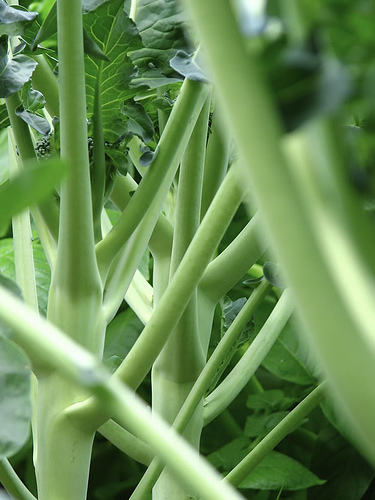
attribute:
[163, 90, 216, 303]
stalk — green , Small 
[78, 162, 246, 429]
stem — green, long, plant's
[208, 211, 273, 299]
stem — green, long, plant's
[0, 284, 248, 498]
stem — green, long, plant's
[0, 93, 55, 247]
stem — green, long, plant's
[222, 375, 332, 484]
stem — green, long, plant's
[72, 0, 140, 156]
broccoli leaf — fresh , green 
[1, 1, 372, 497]
tree — banana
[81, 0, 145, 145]
leaf — flag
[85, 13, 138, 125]
leaf — green, broccoli's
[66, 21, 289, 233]
flower — plant's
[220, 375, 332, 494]
stem — long, green, plant's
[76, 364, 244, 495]
stem — fresh, green 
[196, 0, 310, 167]
stem — long, green, of plant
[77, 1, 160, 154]
leaf — green , fresh 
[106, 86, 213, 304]
stem — light-green, broccoli's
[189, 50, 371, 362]
stem — light-green, broccoli's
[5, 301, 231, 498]
stem — light-green, broccoli's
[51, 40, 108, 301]
stem — light-green, broccoli's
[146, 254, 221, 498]
stem — light-green, broccoli's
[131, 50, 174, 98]
leaf — wind blown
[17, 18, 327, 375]
stem — plant's, long, green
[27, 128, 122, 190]
stock — small, green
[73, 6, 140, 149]
leaf — veined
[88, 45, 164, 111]
banana leaf — wind torn, flag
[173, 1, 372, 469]
plant — green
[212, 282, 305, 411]
stalk — Small , green 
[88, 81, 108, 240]
stem — green, long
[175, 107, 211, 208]
stock — small , green 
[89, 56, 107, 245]
stem — flag leaf's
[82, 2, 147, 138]
broccoli leaf — green, fresh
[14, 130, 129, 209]
banana tree — budded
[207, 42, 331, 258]
broccoli — green , fresh 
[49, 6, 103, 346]
stem — bent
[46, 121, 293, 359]
plant — green , Small 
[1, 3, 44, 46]
broccoli leaf — green , fresh 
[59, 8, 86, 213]
green stem — long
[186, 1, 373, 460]
plant stock — small, green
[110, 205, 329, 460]
broccoli — green , fresh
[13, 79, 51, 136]
banana leaf — curled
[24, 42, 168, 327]
plant — green, small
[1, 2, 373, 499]
stem — green, banana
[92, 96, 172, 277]
plant — Small , green 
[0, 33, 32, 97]
leaf — veined, green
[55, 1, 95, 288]
stem — plant's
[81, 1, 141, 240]
leaf — plant's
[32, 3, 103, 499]
stem — long, green, fresh